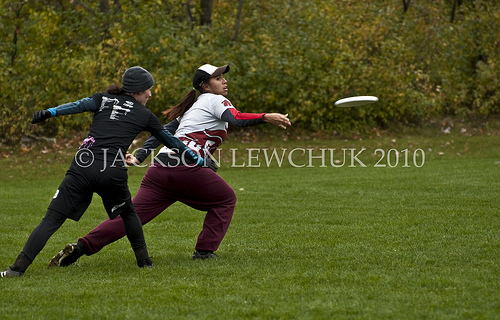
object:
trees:
[2, 2, 499, 141]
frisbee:
[334, 95, 379, 107]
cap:
[192, 63, 230, 88]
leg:
[8, 192, 93, 273]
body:
[46, 93, 291, 270]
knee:
[218, 191, 237, 210]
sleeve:
[213, 95, 236, 121]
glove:
[31, 110, 51, 124]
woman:
[0, 63, 291, 278]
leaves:
[1, 3, 498, 123]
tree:
[1, 0, 237, 142]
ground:
[1, 143, 497, 317]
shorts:
[47, 155, 133, 222]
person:
[0, 66, 218, 279]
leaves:
[251, 43, 300, 84]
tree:
[138, 2, 440, 139]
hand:
[263, 112, 291, 129]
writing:
[287, 148, 426, 168]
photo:
[0, 0, 500, 320]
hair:
[106, 85, 122, 95]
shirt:
[133, 90, 263, 166]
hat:
[192, 63, 230, 87]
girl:
[47, 63, 291, 269]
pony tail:
[161, 87, 197, 120]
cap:
[121, 66, 154, 93]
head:
[121, 66, 154, 93]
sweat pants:
[78, 153, 237, 256]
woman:
[0, 65, 219, 279]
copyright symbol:
[74, 148, 94, 168]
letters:
[98, 96, 134, 121]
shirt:
[46, 92, 204, 166]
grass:
[0, 163, 499, 320]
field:
[0, 145, 499, 320]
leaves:
[248, 27, 359, 76]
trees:
[4, 2, 483, 156]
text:
[100, 147, 287, 172]